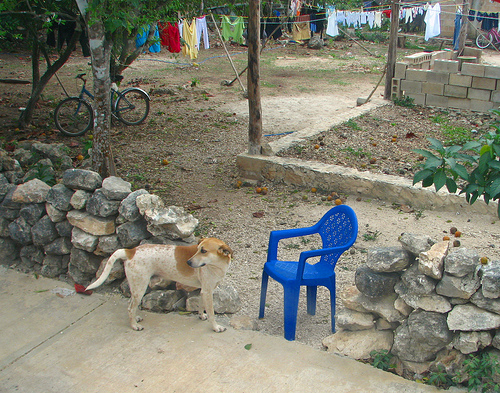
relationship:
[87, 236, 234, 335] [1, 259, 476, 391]
dog standing on sidewalk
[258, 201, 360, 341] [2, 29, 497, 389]
chair in yard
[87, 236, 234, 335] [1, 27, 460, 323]
dog standing in yard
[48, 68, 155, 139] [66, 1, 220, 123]
bicycle leaning against tree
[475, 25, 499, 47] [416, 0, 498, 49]
bike leaning against house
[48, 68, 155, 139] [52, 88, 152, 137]
bicycle with wheels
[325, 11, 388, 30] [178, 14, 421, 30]
laundry hanging on line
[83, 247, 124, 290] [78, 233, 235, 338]
tail of dog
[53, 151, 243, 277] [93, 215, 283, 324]
rocks behind dog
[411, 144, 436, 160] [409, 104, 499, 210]
leaf on tree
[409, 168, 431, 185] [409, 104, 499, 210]
leaf on tree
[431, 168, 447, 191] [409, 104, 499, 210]
leaf on tree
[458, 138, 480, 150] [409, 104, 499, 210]
leaf on tree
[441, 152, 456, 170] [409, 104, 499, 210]
leaf on tree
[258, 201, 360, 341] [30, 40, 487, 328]
chair on ground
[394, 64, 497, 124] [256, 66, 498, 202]
wall by patio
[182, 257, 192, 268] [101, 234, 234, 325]
nose of dog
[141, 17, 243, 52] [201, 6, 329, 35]
clothes hanging from line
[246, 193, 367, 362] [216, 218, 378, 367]
chair in dirt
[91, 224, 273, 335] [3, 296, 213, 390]
dog standing on sidewalk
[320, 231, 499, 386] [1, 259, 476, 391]
wall by he sidewalk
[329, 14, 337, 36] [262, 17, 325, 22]
clothes on clos line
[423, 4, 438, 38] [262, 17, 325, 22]
clothes on clos line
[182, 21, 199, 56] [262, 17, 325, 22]
clothes on clos line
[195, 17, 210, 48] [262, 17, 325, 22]
clothes on clos line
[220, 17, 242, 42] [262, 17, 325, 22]
clothes on clos line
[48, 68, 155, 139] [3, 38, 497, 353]
bicycle in dirt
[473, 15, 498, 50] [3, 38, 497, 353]
bike in dirt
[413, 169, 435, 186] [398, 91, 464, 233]
leaf of a tree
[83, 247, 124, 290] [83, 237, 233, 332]
tail of a dog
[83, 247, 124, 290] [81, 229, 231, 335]
tail of dog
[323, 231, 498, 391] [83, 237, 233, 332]
fence near dog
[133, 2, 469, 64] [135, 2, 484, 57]
clothes on clothesline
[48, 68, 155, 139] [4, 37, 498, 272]
bicycle on ground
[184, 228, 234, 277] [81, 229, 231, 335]
head of dog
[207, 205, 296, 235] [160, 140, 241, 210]
rocks on ground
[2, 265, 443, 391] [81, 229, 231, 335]
cement under dog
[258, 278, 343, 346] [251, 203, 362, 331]
legs of chair